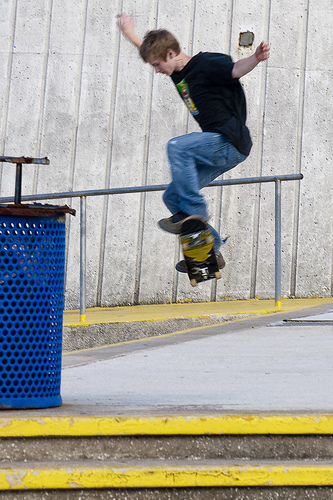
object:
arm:
[198, 52, 257, 80]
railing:
[0, 171, 303, 208]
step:
[1, 407, 331, 460]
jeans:
[161, 133, 247, 254]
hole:
[168, 138, 175, 148]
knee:
[166, 136, 183, 158]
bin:
[0, 217, 65, 412]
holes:
[9, 271, 19, 280]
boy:
[115, 11, 270, 279]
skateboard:
[179, 214, 224, 289]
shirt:
[167, 51, 252, 157]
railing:
[69, 192, 94, 322]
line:
[0, 407, 332, 447]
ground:
[0, 295, 332, 500]